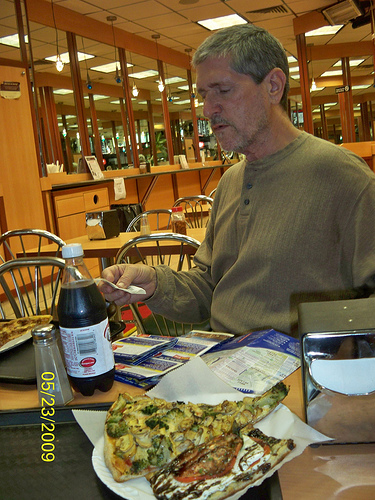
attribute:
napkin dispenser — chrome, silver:
[296, 297, 375, 444]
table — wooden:
[2, 331, 373, 499]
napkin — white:
[92, 275, 147, 300]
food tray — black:
[1, 401, 283, 498]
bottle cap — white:
[61, 240, 86, 261]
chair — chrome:
[114, 231, 205, 336]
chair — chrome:
[3, 258, 82, 320]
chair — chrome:
[126, 206, 190, 230]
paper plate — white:
[88, 393, 294, 499]